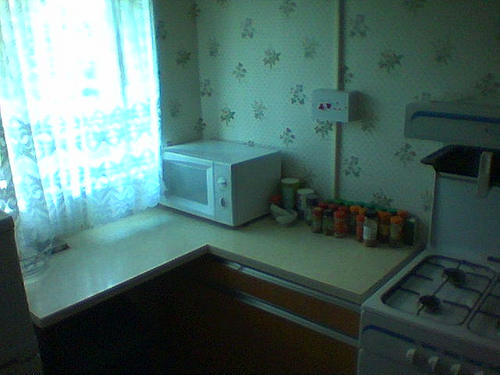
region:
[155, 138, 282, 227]
white microwave on counter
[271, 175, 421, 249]
several spices on counter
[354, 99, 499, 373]
white stove with blue paint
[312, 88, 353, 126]
lightswitch box hanging on wall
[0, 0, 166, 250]
white curtain covering window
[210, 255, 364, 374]
wood and metal cabinets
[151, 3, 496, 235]
wallpaper covering kitchen walls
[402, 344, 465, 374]
white knobs on stove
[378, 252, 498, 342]
black pot holders on stove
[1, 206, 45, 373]
white fridge in corner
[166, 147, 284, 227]
the microwave is white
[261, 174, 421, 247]
spices are on the counter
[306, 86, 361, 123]
switch is on the wall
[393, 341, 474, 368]
the knobs are white in color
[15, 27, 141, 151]
light is coming through the window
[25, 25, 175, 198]
the curtain is transparent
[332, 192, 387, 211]
the bottle toprs are green in color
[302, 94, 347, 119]
the switches are red in color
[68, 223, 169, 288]
reflection is on the counter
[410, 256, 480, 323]
the burner is black in color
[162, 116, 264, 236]
white microwave sitting on the counter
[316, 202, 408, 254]
spices in a group on the counter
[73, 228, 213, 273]
empty counter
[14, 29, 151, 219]
sheers in the window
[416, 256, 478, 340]
gas burners on the stove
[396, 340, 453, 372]
white knobs on the stove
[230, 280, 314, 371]
cabinets below the counter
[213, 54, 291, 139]
flowery wall paper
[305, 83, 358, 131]
outlet on the wall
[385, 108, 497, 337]
blue and white stove by the counter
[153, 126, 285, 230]
microwave on countertop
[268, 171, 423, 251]
bottles of seasoning on countertop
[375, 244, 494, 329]
black metal burners on top of white stove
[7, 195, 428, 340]
tan countertop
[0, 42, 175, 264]
white curtain panels on window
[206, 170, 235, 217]
white knobs on front of microwave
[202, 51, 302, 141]
floral patterned wall paper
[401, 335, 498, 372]
white knobs on front of stove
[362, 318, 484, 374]
blue line on front of stove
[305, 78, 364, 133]
white metal box on wall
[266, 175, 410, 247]
the bottles on the counter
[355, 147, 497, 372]
the old fashioned stove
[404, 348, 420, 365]
the knob on the stove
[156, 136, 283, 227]
the microwave on the counter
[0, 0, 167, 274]
the curtain hanging in the kitchen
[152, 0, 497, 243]
the wall paper on the wall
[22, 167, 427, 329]
the corner part of the counter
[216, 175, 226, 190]
the knob on the microwave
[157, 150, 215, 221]
the door on the microwave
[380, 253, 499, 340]
the burners on the stove